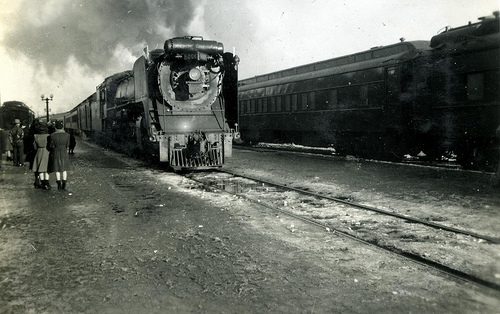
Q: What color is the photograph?
A: Black and white.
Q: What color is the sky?
A: White.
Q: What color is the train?
A: Black.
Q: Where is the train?
A: On the train tracks.